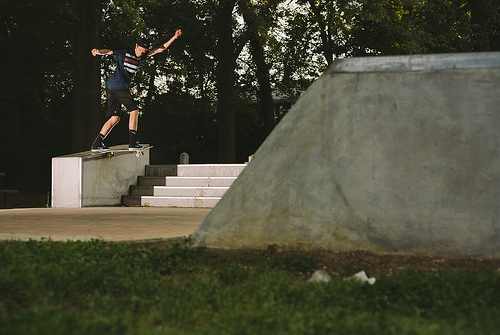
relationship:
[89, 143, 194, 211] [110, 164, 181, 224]
shadows are on pavement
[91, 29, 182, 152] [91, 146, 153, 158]
man skating on skateboard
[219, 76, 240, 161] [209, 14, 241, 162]
trunk in tree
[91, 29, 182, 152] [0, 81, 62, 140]
man in air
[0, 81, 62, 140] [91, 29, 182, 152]
air around man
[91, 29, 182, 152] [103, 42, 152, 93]
man with shirt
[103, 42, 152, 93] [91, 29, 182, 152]
shirt on man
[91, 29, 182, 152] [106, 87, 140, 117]
man wearing shorts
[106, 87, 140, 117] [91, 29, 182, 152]
shorts on man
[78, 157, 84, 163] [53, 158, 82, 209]
edge of wall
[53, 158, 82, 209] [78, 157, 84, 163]
wall with edge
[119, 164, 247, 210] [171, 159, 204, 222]
stairs in a set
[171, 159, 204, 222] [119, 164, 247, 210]
set of stairs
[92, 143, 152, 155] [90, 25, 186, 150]
skateboard under man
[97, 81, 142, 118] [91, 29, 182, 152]
shorts on man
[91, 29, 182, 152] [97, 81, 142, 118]
man with shorts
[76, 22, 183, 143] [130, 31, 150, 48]
man with hat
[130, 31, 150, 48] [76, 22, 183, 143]
hat on man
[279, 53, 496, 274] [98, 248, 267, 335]
concrete on ground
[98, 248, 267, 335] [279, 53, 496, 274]
ground under concrete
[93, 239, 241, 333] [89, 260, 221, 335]
grass under patch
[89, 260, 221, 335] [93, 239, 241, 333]
patch with grass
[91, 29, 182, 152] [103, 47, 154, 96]
man belonging to shirt